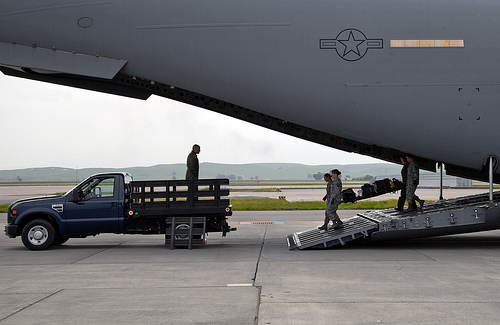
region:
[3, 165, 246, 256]
truck under the plane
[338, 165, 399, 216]
person being transported on stretcher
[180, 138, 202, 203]
man standing in back of truck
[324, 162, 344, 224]
serviceman walking down incline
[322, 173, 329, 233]
serviceman walking down incline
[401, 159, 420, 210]
serviceman walking down incline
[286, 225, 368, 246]
incline of the plane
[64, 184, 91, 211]
mirror on the truck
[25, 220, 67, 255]
tire on the truck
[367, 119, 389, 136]
this is a plane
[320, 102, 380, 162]
the plane is metal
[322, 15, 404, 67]
this is a logo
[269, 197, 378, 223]
these are soliders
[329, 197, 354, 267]
this is a uniform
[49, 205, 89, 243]
this is a truck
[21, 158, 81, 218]
the truck is blue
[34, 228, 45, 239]
this is a wheel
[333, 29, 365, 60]
black star outline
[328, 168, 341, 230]
woman in uniform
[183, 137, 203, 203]
man standing in truck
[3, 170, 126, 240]
dark blue truck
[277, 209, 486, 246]
silver airplane ramp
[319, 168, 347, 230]
soldiers walking on ramp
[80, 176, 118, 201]
drivers side window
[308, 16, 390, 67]
black emblem on plane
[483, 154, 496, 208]
silver pole on ramp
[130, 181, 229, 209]
black sides on truck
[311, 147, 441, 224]
military personel coming out of plane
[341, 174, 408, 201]
body on the strecher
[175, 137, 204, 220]
person standing in the truck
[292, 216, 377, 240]
ramp where people walk down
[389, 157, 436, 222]
two people walking behind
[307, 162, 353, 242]
two females coming down ramp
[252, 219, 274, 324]
crack in runway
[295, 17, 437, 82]
insignia on the plane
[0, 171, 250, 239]
truck is parked near plane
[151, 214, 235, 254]
item made of wood by the truck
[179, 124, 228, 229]
a man in the van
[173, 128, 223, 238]
a man standing in the jeep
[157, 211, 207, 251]
a chair in the ground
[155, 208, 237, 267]
a chair near the plane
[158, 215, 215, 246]
a chair near the jeep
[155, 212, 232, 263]
a chair before the people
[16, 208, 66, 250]
front tire of the jeep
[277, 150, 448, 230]
a group of people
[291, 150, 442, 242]
a group of people carrying lagugage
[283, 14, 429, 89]
a logo in the plane